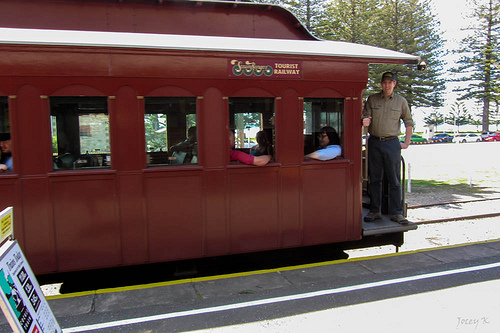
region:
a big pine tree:
[454, 2, 496, 123]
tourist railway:
[232, 56, 312, 78]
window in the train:
[37, 85, 139, 187]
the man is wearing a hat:
[358, 67, 414, 232]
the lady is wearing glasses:
[304, 114, 345, 161]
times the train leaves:
[6, 252, 54, 315]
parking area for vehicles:
[416, 122, 497, 145]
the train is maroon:
[13, 11, 153, 264]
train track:
[422, 197, 496, 225]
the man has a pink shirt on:
[229, 126, 260, 171]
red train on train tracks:
[1, 0, 431, 278]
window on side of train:
[136, 90, 206, 173]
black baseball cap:
[378, 68, 397, 84]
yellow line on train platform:
[61, 223, 487, 310]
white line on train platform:
[65, 264, 497, 331]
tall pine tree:
[443, 2, 498, 134]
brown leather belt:
[367, 130, 397, 142]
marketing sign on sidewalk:
[1, 203, 58, 330]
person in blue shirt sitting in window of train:
[304, 121, 343, 163]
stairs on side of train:
[358, 150, 418, 240]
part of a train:
[305, 207, 317, 215]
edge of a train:
[261, 236, 263, 241]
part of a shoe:
[378, 197, 388, 210]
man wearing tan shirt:
[380, 110, 390, 127]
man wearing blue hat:
[393, 75, 397, 80]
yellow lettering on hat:
[383, 70, 395, 79]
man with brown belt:
[362, 132, 398, 142]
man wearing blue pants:
[371, 160, 378, 184]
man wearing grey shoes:
[363, 208, 415, 232]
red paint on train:
[243, 195, 276, 221]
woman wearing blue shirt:
[324, 150, 332, 157]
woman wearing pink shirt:
[239, 153, 249, 159]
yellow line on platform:
[146, 282, 163, 289]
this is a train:
[13, 12, 450, 287]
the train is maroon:
[16, 10, 416, 298]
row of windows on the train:
[15, 75, 374, 193]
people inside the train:
[29, 90, 370, 197]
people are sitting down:
[85, 87, 360, 190]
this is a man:
[354, 62, 430, 235]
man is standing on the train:
[345, 27, 444, 285]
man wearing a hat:
[375, 53, 403, 93]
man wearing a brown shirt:
[358, 78, 413, 140]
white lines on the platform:
[89, 248, 494, 330]